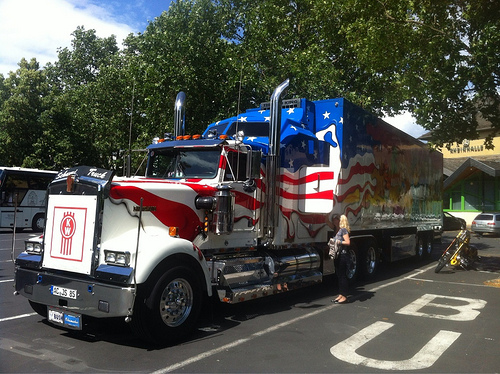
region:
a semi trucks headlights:
[104, 242, 160, 294]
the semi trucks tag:
[52, 283, 95, 315]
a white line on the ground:
[290, 309, 310, 328]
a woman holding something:
[323, 223, 344, 261]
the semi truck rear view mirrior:
[238, 153, 271, 181]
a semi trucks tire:
[136, 296, 180, 352]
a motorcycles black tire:
[433, 246, 460, 294]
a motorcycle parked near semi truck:
[435, 227, 495, 282]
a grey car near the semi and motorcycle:
[472, 222, 497, 240]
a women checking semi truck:
[324, 211, 360, 257]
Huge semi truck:
[35, 82, 465, 326]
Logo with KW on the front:
[43, 190, 97, 272]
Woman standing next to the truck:
[326, 207, 358, 307]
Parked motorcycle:
[417, 209, 485, 274]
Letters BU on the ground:
[332, 273, 478, 371]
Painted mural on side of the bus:
[321, 108, 443, 220]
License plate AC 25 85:
[43, 278, 85, 300]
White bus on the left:
[2, 158, 49, 224]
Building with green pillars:
[447, 182, 488, 210]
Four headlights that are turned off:
[16, 234, 143, 266]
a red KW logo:
[53, 205, 83, 258]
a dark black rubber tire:
[141, 265, 205, 342]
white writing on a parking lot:
[328, 291, 484, 367]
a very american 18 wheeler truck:
[13, 87, 446, 331]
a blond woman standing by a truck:
[320, 216, 354, 305]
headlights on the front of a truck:
[23, 240, 130, 265]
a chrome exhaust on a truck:
[257, 77, 297, 237]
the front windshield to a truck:
[150, 148, 216, 176]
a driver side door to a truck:
[224, 151, 252, 225]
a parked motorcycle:
[434, 230, 481, 276]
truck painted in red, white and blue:
[16, 75, 455, 349]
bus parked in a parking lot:
[1, 162, 59, 237]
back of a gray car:
[469, 209, 499, 239]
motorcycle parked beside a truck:
[434, 223, 489, 275]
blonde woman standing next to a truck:
[326, 213, 359, 311]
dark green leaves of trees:
[3, 35, 499, 158]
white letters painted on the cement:
[322, 286, 495, 370]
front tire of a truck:
[138, 252, 218, 359]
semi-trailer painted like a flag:
[202, 76, 452, 237]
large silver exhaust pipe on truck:
[258, 76, 301, 245]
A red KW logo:
[50, 208, 87, 261]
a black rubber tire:
[143, 265, 205, 337]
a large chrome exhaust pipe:
[263, 77, 293, 231]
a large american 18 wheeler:
[14, 95, 446, 331]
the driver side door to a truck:
[222, 147, 257, 234]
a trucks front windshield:
[148, 145, 220, 180]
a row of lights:
[150, 132, 232, 145]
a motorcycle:
[434, 229, 484, 270]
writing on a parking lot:
[333, 293, 490, 372]